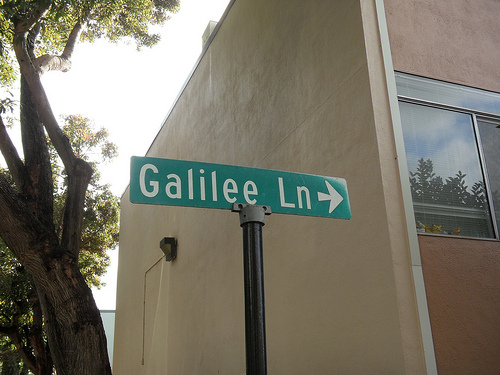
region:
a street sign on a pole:
[85, 117, 470, 339]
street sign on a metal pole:
[114, 79, 385, 371]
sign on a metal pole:
[98, 96, 353, 373]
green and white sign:
[87, 88, 490, 371]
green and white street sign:
[122, 128, 351, 373]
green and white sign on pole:
[110, 122, 393, 374]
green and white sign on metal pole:
[112, 105, 379, 370]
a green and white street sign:
[115, 110, 389, 367]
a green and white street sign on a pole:
[116, 127, 408, 372]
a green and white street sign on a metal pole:
[80, 127, 424, 372]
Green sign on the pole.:
[113, 91, 453, 260]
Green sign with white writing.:
[66, 100, 402, 287]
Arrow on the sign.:
[308, 172, 362, 220]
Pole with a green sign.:
[109, 134, 334, 368]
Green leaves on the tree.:
[13, 95, 125, 304]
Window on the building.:
[371, 59, 491, 248]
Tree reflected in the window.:
[371, 90, 496, 242]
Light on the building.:
[151, 217, 192, 272]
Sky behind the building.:
[55, 75, 149, 177]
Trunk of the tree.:
[27, 226, 95, 361]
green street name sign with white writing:
[132, 157, 355, 221]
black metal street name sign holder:
[236, 203, 278, 373]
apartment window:
[397, 74, 499, 231]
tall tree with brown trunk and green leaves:
[0, 17, 115, 370]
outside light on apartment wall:
[156, 237, 181, 261]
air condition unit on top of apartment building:
[197, 16, 222, 46]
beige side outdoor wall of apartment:
[118, 0, 428, 372]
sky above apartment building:
[61, 42, 179, 112]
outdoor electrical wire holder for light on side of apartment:
[128, 267, 168, 369]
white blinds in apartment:
[402, 210, 494, 237]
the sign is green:
[115, 129, 372, 259]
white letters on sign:
[131, 156, 320, 217]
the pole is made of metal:
[238, 220, 271, 371]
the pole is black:
[227, 200, 275, 362]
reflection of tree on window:
[409, 147, 497, 232]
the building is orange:
[383, 0, 493, 371]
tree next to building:
[0, 2, 200, 367]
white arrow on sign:
[311, 176, 353, 215]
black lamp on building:
[148, 224, 191, 276]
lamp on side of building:
[147, 224, 192, 266]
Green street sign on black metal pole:
[130, 153, 352, 221]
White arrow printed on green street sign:
[315, 173, 344, 215]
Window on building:
[393, 70, 498, 246]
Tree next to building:
[0, 0, 181, 372]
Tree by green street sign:
[0, 0, 180, 374]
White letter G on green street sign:
[140, 162, 159, 198]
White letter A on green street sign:
[164, 171, 184, 201]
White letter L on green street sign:
[185, 165, 197, 201]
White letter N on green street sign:
[297, 182, 310, 211]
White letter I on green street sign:
[198, 165, 207, 205]